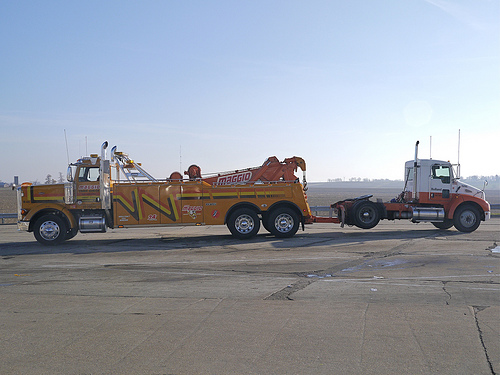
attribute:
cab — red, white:
[323, 150, 493, 247]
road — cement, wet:
[235, 243, 409, 339]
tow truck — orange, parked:
[34, 145, 316, 238]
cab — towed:
[346, 138, 492, 267]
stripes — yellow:
[72, 175, 279, 224]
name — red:
[213, 165, 259, 189]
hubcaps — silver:
[35, 212, 77, 244]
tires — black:
[225, 203, 305, 251]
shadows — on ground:
[23, 225, 443, 250]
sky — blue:
[138, 12, 205, 97]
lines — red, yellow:
[101, 190, 206, 221]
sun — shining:
[388, 72, 494, 156]